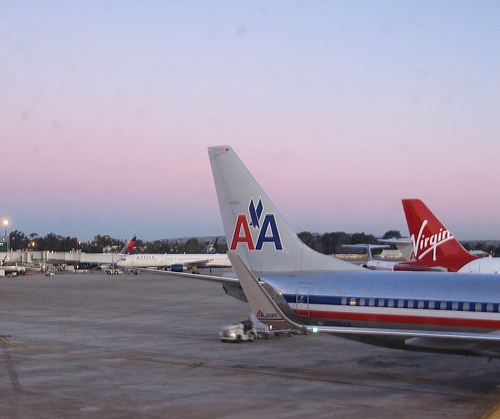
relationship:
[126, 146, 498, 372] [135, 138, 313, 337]
plane has a tail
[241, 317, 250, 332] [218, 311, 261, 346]
man driving tram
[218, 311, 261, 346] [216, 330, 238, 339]
tram has headlights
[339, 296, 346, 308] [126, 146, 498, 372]
window on side of plane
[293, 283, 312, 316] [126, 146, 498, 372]
door on side of plane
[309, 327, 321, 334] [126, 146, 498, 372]
light on side of plane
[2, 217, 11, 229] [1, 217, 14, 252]
light on top of pole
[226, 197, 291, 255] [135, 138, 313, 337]
logo on tail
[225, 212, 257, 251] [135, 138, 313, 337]
letter on tail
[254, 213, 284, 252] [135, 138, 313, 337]
letter on tail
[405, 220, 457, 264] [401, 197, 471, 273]
word on tail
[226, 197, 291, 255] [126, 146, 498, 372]
logo on tail of plane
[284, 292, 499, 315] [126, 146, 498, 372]
stripe on side of plane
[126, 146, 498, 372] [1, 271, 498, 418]
plane standing on ground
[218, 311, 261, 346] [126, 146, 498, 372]
tram beside plane